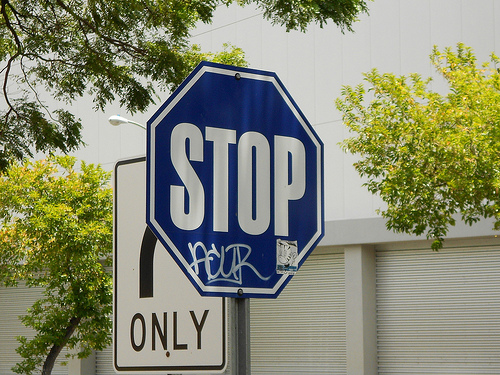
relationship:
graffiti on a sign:
[161, 219, 278, 310] [83, 21, 383, 334]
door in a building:
[242, 251, 344, 371] [214, 212, 498, 373]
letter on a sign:
[271, 133, 308, 235] [144, 60, 323, 297]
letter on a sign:
[169, 122, 205, 230] [144, 60, 323, 297]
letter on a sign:
[205, 125, 236, 234] [144, 60, 323, 297]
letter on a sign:
[237, 130, 271, 235] [144, 60, 323, 297]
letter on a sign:
[274, 135, 302, 235] [144, 60, 323, 297]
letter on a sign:
[185, 241, 272, 286] [144, 60, 323, 297]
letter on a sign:
[162, 117, 202, 244] [119, 54, 337, 321]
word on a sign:
[123, 305, 209, 354] [113, 155, 226, 372]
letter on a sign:
[129, 312, 146, 352] [113, 155, 226, 372]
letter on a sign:
[129, 312, 146, 352] [92, 158, 232, 369]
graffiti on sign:
[161, 219, 278, 310] [144, 60, 323, 297]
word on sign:
[123, 305, 209, 354] [113, 155, 226, 372]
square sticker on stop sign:
[275, 237, 301, 275] [147, 57, 329, 301]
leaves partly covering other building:
[331, 39, 498, 254] [1, 204, 495, 371]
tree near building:
[327, 40, 498, 257] [1, 204, 495, 371]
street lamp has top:
[81, 89, 196, 157] [99, 106, 159, 152]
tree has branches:
[4, 6, 373, 242] [11, 0, 363, 130]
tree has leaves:
[4, 6, 373, 242] [8, 7, 139, 83]